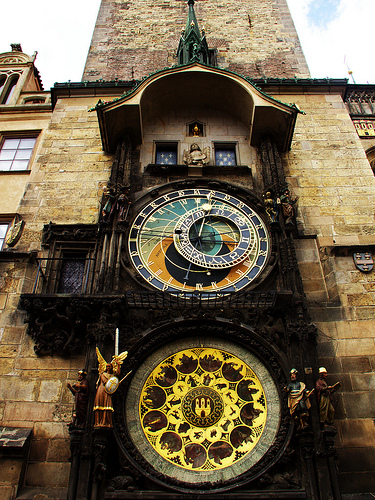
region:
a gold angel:
[91, 348, 131, 420]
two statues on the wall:
[282, 367, 338, 426]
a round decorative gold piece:
[139, 346, 265, 474]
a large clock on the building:
[127, 185, 267, 298]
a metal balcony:
[30, 252, 92, 292]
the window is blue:
[157, 146, 176, 165]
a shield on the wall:
[351, 251, 371, 272]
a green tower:
[169, 2, 215, 64]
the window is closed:
[1, 136, 32, 169]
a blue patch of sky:
[305, 1, 339, 28]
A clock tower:
[89, 29, 310, 489]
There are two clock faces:
[129, 188, 280, 493]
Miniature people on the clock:
[64, 344, 354, 435]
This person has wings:
[88, 344, 133, 424]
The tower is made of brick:
[0, 354, 69, 423]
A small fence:
[39, 251, 100, 294]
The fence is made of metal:
[39, 255, 97, 293]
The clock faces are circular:
[129, 184, 282, 487]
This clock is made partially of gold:
[142, 353, 253, 467]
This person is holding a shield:
[103, 372, 121, 398]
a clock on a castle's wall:
[134, 182, 290, 297]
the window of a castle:
[150, 136, 183, 174]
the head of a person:
[317, 365, 327, 375]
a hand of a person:
[315, 379, 330, 384]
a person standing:
[315, 366, 354, 445]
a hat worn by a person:
[319, 365, 328, 374]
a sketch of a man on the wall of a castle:
[182, 138, 211, 165]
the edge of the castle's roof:
[50, 76, 73, 95]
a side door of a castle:
[4, 72, 22, 109]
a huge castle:
[27, 7, 368, 427]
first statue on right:
[311, 363, 342, 431]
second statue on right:
[279, 365, 311, 431]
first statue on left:
[60, 363, 90, 427]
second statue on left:
[90, 345, 128, 435]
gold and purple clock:
[137, 343, 261, 497]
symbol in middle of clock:
[193, 395, 211, 419]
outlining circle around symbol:
[200, 387, 212, 396]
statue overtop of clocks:
[181, 138, 210, 168]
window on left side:
[153, 139, 180, 165]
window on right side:
[211, 139, 238, 165]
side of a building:
[9, 18, 373, 481]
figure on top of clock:
[180, 139, 213, 165]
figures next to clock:
[264, 180, 298, 229]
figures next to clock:
[92, 178, 130, 220]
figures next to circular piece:
[285, 362, 352, 430]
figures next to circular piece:
[66, 353, 113, 423]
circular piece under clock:
[124, 334, 282, 464]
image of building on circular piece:
[189, 396, 216, 414]